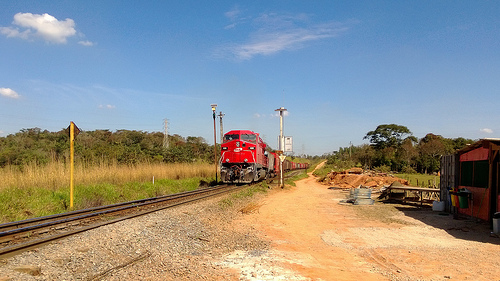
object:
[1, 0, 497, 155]
sky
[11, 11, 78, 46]
clouds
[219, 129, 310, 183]
train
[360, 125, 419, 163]
trees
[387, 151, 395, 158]
leaves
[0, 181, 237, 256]
railway line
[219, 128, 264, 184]
front car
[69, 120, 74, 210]
pole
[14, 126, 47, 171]
trees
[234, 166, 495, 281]
dirt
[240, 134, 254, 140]
window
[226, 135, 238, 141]
window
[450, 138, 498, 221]
building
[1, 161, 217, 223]
grass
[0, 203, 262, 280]
gravel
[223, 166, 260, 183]
wheels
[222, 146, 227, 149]
light